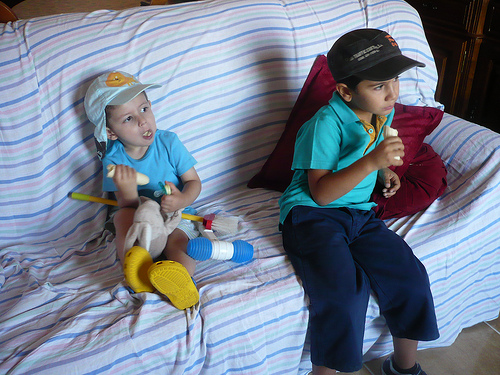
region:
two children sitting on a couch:
[56, 25, 466, 340]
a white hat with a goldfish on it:
[82, 68, 166, 149]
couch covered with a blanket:
[3, 2, 492, 360]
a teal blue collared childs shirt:
[288, 92, 400, 226]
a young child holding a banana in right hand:
[78, 65, 207, 216]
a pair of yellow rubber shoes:
[119, 243, 209, 307]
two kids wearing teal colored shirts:
[66, 27, 416, 224]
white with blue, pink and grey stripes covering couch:
[9, 10, 484, 373]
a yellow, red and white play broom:
[63, 185, 245, 242]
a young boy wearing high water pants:
[288, 22, 447, 373]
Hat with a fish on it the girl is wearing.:
[80, 69, 162, 96]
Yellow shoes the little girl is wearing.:
[148, 259, 190, 309]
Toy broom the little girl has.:
[186, 204, 248, 229]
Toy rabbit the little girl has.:
[128, 199, 180, 251]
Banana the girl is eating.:
[104, 167, 156, 184]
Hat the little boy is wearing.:
[323, 25, 425, 90]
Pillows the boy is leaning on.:
[404, 118, 424, 201]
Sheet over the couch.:
[16, 164, 58, 373]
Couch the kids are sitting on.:
[32, 35, 435, 327]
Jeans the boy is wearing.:
[323, 265, 340, 327]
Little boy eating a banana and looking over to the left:
[61, 65, 208, 217]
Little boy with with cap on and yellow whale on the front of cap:
[32, 49, 199, 158]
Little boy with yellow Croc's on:
[72, 48, 215, 333]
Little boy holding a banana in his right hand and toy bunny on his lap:
[66, 49, 264, 320]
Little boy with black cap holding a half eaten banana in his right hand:
[298, 24, 428, 247]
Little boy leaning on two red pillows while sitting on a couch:
[251, 26, 460, 221]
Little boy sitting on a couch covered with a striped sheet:
[262, 13, 492, 374]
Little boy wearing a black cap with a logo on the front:
[265, 10, 433, 127]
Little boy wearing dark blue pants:
[258, 20, 463, 373]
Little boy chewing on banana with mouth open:
[71, 63, 176, 159]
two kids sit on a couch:
[81, 28, 427, 373]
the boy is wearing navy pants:
[283, 206, 438, 371]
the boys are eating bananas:
[83, 26, 440, 373]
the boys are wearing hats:
[82, 30, 424, 143]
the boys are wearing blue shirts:
[103, 105, 394, 222]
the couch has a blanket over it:
[0, 2, 498, 372]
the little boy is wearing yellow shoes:
[121, 247, 198, 310]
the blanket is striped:
[1, 0, 498, 372]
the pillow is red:
[249, 52, 445, 219]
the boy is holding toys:
[71, 71, 255, 307]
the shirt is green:
[314, 117, 388, 212]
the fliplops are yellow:
[110, 252, 203, 305]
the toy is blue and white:
[193, 233, 273, 268]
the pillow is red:
[303, 66, 429, 206]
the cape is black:
[328, 33, 420, 80]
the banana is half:
[105, 168, 148, 187]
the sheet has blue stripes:
[206, 74, 281, 164]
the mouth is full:
[140, 127, 164, 142]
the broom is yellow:
[70, 199, 204, 226]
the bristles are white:
[215, 208, 245, 242]